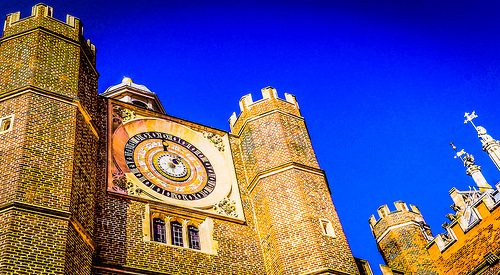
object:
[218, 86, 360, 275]
tower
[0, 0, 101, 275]
tower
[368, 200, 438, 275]
tower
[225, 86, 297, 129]
flags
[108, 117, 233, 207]
clock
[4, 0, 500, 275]
brown castle